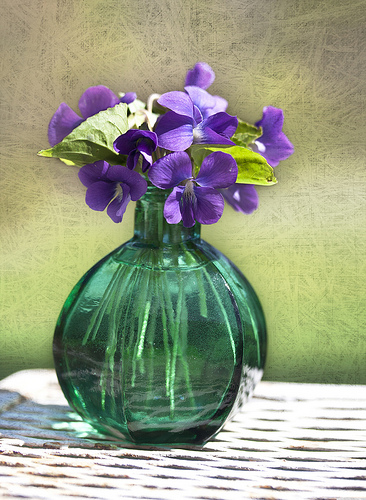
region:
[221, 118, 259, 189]
Green leaf in vase.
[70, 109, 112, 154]
Green leaf in vase.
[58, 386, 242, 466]
Vase sitting on white surface.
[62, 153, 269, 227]
Flower bouquet in green vase.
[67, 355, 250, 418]
Vase is green glass.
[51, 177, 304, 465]
the vase is green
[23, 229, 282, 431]
the vase is made of glass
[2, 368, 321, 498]
the table has holes in it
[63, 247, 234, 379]
stems of the floewrs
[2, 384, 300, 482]
the table is white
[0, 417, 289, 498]
the table is metal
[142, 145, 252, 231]
the flower is purple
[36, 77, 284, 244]
a bunch of flowers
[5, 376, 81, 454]
shadow of the vase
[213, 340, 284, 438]
reflection of the table in the vase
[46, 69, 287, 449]
Green vase with flowers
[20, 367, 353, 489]
Vase on white table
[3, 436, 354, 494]
White table is wicker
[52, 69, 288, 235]
Purple flowers in vase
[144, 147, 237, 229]
Purple flower hanging over the side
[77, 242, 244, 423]
Stems in the water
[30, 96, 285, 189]
Flowers with green leaves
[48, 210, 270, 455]
A vase with blue green glass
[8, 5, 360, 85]
A patterned background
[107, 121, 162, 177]
A wilted purple flower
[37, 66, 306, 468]
flowers in a vase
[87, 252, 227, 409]
bundle of gree stems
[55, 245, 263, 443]
stems visible in the vase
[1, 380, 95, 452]
shadow from the vase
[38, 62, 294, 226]
small bouquet of purple flowers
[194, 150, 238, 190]
round purple petal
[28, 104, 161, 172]
green leaf on the bouquet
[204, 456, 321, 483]
four thin slits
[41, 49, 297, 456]
purple flowers in a green vase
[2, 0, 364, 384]
scratches all over the wall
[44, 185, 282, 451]
green vase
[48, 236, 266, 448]
green vase filled with water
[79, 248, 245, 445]
green stems in the water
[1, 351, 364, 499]
white grate under the vase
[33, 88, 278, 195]
green leaves in the flowers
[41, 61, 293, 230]
purple and green flowers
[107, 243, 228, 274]
water line in the vase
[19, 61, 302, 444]
purple and green vase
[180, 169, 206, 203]
center of a purple flower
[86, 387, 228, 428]
ends of the flower stems